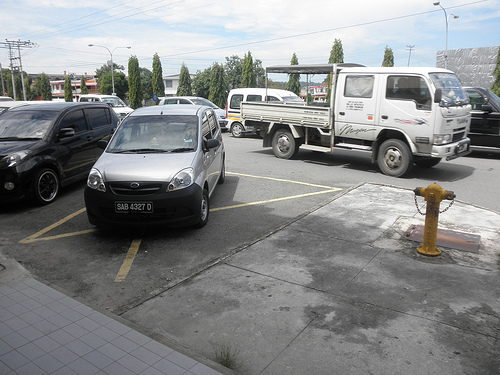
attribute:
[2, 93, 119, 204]
car — black 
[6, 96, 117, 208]
car — black 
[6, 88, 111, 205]
car — black 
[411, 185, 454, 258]
hydrant — yellow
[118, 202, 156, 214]
license plate — black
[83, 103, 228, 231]
car — silver, parked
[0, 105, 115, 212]
car — black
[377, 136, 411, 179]
tire — front right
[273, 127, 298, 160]
tire — in back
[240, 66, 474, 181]
truck — white, flat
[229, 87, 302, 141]
van — white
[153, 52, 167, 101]
tree — thin, tall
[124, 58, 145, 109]
tree — thin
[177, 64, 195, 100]
tree — thin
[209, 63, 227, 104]
tree — thin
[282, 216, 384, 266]
mark — wet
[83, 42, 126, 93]
light — street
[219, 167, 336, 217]
lines — yellow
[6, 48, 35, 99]
pole — metal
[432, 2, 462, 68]
street light — tall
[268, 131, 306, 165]
wheel — parted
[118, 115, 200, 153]
glass — parted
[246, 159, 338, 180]
floor — parted